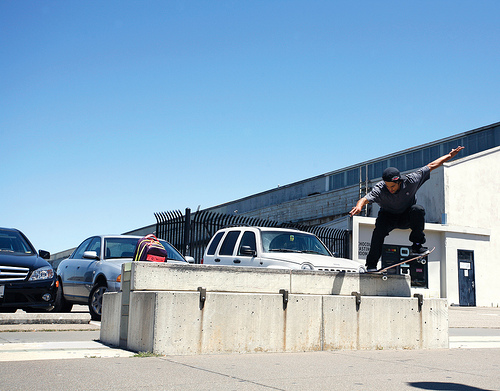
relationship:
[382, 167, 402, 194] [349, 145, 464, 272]
head of guy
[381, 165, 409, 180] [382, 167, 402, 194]
hat on head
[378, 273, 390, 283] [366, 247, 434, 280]
wheel of skateboard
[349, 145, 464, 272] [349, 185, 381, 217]
guy has arm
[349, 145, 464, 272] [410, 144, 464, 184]
guy has arm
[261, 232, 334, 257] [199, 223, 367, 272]
window of vehicle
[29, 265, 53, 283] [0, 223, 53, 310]
headlight of car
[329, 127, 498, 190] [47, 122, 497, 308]
windows on building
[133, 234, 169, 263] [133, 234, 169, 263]
part of part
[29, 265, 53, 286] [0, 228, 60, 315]
headlight on car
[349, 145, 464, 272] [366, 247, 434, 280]
guy doing a trick on skateboard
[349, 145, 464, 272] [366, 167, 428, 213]
guy wearing shirt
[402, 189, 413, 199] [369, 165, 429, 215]
symbol on shirt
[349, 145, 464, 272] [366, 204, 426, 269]
guy wearing pants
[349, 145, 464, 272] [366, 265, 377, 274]
guy wearing sneaker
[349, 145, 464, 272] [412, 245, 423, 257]
guy wearing sneaker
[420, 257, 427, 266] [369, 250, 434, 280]
wheel on right of board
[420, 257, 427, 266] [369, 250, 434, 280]
wheel on board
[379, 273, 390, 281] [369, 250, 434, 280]
wheel on board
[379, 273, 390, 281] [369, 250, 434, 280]
wheel on left of board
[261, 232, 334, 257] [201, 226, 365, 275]
window of jeep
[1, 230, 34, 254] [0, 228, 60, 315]
window of car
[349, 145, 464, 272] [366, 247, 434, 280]
guy on skateboard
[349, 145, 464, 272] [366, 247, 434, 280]
guy performing grind on skateboard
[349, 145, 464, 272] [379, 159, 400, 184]
guy has hat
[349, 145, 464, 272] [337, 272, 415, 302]
guy on slab